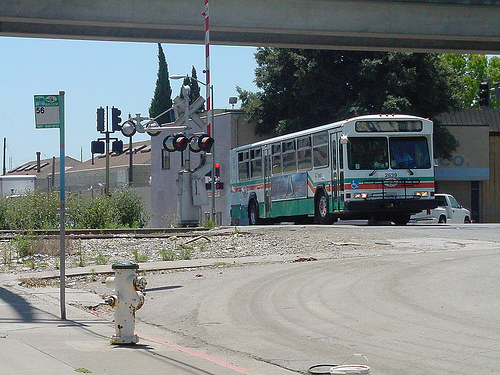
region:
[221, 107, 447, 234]
bus on a street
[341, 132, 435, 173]
front windshield on a bus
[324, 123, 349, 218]
door on a bus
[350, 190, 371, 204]
front headlights on a bus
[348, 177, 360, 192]
blue and white handicap sign on a bus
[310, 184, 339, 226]
front wheel on a bus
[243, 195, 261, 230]
rear wheel on a bus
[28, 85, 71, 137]
sign on a pole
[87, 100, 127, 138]
traffic signals on a pole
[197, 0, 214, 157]
red and white railroad crossing arm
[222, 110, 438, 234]
green, red and white bus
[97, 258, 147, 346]
white fire hydrant with green cap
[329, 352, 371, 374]
white bucket with handle up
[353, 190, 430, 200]
lit square headlights on bus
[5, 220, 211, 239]
rusty railroad tracks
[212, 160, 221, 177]
red traffic signal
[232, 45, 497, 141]
green leaves on trees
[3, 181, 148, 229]
weeds growing on side of tracks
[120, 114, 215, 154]
red railroad crossing lights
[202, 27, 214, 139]
red and white railroad crossing barrier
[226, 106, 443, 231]
A green and white city bus.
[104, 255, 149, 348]
A white fire hydrant.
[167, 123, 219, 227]
Railroad track crossing signal.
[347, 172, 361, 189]
A handicap emblem on front of the bus.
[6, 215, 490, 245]
A railroad track crossing the street.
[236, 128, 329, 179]
Passenger windows on the bus.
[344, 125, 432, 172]
Front windshield of the bus.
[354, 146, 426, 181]
Windshield wipers on the bus.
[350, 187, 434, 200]
Headlights on front of the bus are on.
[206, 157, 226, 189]
A traffic signal that has turned red.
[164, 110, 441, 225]
a bus crossing a railroad track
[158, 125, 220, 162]
lights at a railroad crossing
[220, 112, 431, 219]
a white bus with a green and red stripe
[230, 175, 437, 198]
a green and red stripe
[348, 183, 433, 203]
headlights on a bus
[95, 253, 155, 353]
a fire hydrant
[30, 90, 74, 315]
a sign on a pole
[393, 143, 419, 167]
a bus driver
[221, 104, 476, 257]
a bus on a road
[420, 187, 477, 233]
a white pickup behind a bus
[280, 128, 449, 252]
white bus on track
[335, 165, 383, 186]
green paint on bus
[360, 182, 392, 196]
red paint on bus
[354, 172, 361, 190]
white sign on bus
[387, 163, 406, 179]
black number on bus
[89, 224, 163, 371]
white hydrant on road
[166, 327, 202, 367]
red line on road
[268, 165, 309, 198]
silver sign on bus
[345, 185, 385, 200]
bright light on bus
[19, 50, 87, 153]
metal sign on post